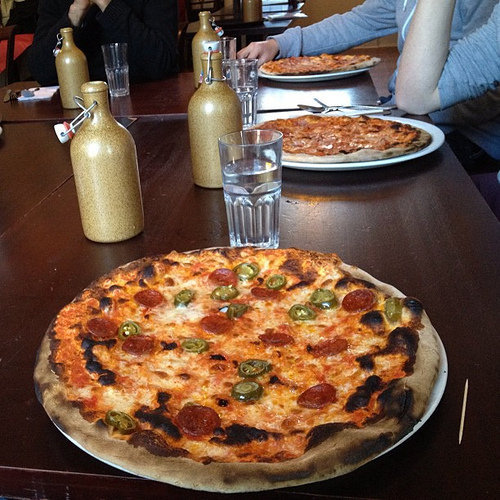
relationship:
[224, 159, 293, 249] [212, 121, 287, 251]
water has glass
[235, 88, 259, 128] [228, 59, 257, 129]
water has glass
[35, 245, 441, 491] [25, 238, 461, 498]
pie on plate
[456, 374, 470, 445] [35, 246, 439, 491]
toothpick next to pizza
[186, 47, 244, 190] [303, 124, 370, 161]
bottle next to pizza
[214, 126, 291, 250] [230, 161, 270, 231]
glass has water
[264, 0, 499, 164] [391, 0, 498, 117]
jumper folded at arm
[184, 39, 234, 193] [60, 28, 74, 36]
bottle has brim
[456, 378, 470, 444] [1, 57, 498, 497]
toothpick on table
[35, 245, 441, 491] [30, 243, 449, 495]
pie on dish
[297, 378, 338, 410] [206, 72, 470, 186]
pepperoni on pizza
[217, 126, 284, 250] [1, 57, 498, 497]
glass on table